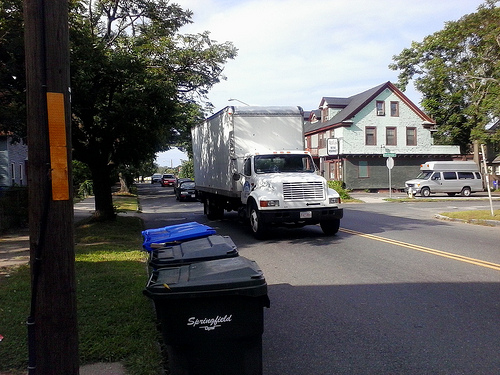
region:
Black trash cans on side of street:
[139, 239, 275, 374]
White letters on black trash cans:
[179, 308, 237, 342]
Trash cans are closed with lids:
[133, 228, 283, 373]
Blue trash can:
[134, 213, 222, 255]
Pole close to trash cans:
[16, 1, 98, 373]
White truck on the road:
[175, 91, 361, 241]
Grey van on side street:
[398, 150, 490, 205]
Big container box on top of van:
[412, 152, 480, 172]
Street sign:
[381, 146, 400, 196]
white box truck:
[173, 101, 350, 238]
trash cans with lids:
[130, 223, 272, 374]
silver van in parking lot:
[402, 156, 497, 210]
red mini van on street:
[160, 171, 178, 188]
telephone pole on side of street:
[8, 3, 93, 370]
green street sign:
[376, 144, 403, 201]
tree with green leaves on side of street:
[75, 11, 179, 257]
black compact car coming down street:
[174, 178, 199, 207]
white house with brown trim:
[317, 88, 454, 197]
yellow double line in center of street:
[329, 226, 496, 275]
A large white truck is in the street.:
[185, 110, 343, 245]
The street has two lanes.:
[125, 150, 495, 367]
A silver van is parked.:
[397, 150, 487, 195]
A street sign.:
[376, 141, 398, 201]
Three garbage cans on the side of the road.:
[135, 215, 295, 370]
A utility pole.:
[10, 0, 95, 365]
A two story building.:
[305, 90, 460, 190]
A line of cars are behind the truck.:
[145, 101, 341, 231]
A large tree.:
[10, 0, 207, 211]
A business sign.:
[325, 136, 340, 157]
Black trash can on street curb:
[141, 265, 287, 373]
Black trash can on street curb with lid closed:
[150, 235, 249, 265]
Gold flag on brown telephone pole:
[36, 70, 78, 234]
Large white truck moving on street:
[178, 101, 349, 256]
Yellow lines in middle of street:
[363, 219, 494, 289]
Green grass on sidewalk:
[88, 257, 143, 352]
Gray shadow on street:
[303, 277, 489, 361]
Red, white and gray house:
[315, 62, 464, 157]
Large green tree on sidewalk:
[58, 18, 170, 228]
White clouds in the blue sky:
[238, 10, 398, 84]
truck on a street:
[177, 94, 372, 254]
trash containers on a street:
[135, 207, 281, 374]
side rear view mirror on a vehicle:
[226, 164, 256, 186]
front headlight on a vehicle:
[253, 194, 282, 211]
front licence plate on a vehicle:
[293, 204, 318, 226]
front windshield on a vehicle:
[249, 148, 319, 178]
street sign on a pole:
[378, 143, 403, 202]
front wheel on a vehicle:
[417, 182, 435, 202]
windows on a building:
[358, 120, 421, 150]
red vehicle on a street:
[155, 170, 185, 192]